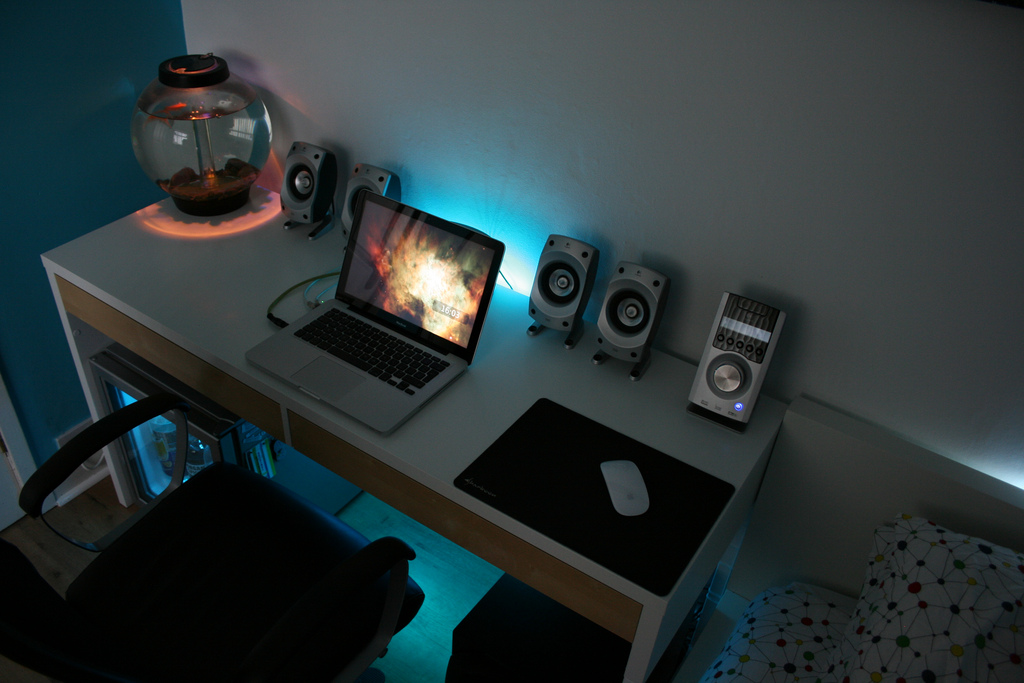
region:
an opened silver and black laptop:
[244, 194, 505, 438]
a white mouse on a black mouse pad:
[599, 451, 651, 521]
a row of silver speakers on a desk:
[263, 140, 780, 431]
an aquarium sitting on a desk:
[133, 52, 273, 215]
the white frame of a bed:
[658, 394, 1020, 679]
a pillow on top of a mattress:
[819, 508, 1019, 679]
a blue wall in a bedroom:
[1, 4, 186, 467]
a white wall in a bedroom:
[182, 2, 1020, 489]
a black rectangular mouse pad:
[453, 397, 738, 597]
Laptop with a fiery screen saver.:
[237, 190, 509, 434]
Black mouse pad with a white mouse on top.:
[451, 401, 737, 598]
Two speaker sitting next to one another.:
[522, 234, 672, 380]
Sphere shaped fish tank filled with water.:
[129, 47, 275, 218]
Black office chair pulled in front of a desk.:
[2, 391, 430, 680]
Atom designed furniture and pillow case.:
[699, 514, 1022, 679]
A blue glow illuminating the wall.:
[405, 164, 570, 316]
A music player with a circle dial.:
[685, 282, 790, 432]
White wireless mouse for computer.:
[597, 459, 654, 514]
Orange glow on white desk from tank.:
[128, 184, 296, 239]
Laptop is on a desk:
[222, 166, 524, 449]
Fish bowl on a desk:
[128, 42, 288, 224]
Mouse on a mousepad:
[589, 428, 666, 534]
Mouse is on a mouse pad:
[588, 441, 655, 527]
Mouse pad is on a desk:
[444, 383, 751, 611]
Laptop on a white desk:
[234, 175, 523, 455]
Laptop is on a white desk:
[235, 187, 531, 453]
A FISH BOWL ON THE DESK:
[125, 47, 280, 225]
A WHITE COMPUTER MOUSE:
[589, 454, 660, 524]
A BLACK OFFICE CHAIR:
[2, 384, 430, 676]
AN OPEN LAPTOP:
[238, 181, 508, 442]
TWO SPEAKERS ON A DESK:
[520, 226, 679, 388]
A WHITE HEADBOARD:
[721, 384, 1017, 612]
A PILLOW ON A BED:
[819, 497, 1017, 676]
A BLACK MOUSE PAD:
[447, 390, 745, 603]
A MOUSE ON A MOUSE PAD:
[447, 391, 743, 604]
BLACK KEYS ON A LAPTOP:
[285, 301, 466, 407]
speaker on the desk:
[590, 260, 654, 388]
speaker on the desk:
[266, 126, 337, 243]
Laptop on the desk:
[249, 186, 512, 455]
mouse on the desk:
[588, 443, 661, 535]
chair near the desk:
[9, 350, 436, 680]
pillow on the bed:
[836, 499, 1023, 678]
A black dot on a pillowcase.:
[891, 629, 914, 643]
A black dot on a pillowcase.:
[915, 590, 931, 611]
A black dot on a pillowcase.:
[907, 577, 923, 590]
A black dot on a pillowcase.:
[955, 554, 968, 568]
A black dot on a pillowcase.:
[878, 519, 882, 529]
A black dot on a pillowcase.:
[800, 612, 820, 625]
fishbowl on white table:
[115, 47, 311, 238]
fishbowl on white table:
[120, 48, 316, 246]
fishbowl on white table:
[107, 45, 329, 257]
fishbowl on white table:
[112, 41, 328, 241]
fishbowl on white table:
[115, 45, 319, 262]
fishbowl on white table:
[101, 45, 329, 251]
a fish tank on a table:
[124, 40, 280, 222]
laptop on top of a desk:
[233, 179, 508, 437]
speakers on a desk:
[522, 224, 675, 381]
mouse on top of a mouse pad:
[447, 387, 738, 610]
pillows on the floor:
[690, 499, 1011, 678]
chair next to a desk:
[4, 390, 434, 676]